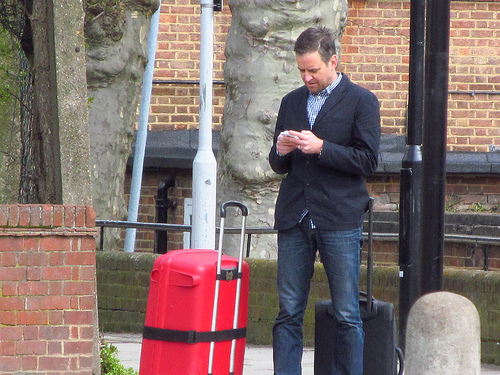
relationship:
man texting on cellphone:
[265, 26, 380, 374] [261, 100, 335, 148]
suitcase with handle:
[318, 300, 399, 373] [351, 188, 389, 302]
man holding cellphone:
[265, 26, 380, 374] [277, 129, 299, 141]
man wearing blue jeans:
[265, 26, 380, 374] [267, 229, 367, 374]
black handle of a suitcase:
[215, 201, 250, 219] [162, 204, 317, 372]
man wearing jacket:
[265, 26, 380, 374] [268, 74, 380, 234]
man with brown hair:
[265, 26, 380, 374] [293, 26, 338, 65]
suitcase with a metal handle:
[75, 199, 296, 369] [205, 200, 247, 372]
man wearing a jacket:
[265, 26, 380, 374] [268, 74, 380, 234]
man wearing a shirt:
[265, 26, 380, 374] [307, 73, 344, 130]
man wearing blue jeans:
[265, 0, 446, 228] [271, 214, 368, 372]